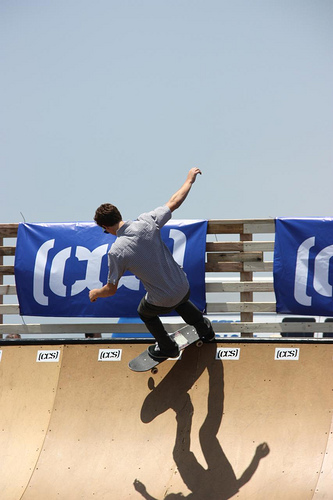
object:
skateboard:
[128, 315, 213, 373]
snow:
[253, 313, 284, 325]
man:
[89, 168, 216, 360]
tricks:
[92, 152, 230, 438]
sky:
[17, 15, 311, 133]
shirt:
[107, 205, 190, 307]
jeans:
[138, 288, 213, 351]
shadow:
[132, 336, 270, 498]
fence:
[206, 217, 275, 339]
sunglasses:
[103, 230, 109, 235]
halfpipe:
[0, 330, 332, 498]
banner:
[14, 218, 208, 316]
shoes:
[147, 335, 181, 360]